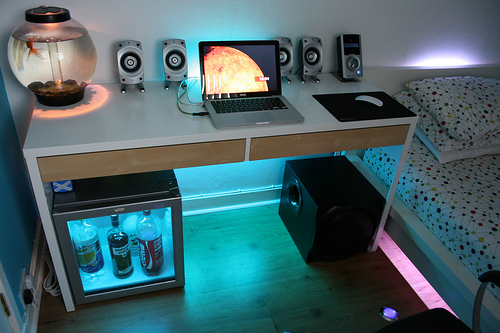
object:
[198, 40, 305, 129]
computer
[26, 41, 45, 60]
goldfish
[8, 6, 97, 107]
aquarium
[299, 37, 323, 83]
speaker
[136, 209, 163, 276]
bottle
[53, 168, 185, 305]
fridge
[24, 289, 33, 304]
outlet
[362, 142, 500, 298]
sheet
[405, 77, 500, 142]
pillow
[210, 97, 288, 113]
keyboard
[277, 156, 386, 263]
sub woofer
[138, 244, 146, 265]
cola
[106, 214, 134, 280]
bottle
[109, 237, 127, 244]
drink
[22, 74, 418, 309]
desk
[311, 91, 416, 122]
mousepad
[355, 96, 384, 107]
mouse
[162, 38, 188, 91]
speaker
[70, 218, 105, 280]
beverages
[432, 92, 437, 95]
color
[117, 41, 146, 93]
speaker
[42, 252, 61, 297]
cord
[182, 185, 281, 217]
baseboard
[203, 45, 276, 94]
screen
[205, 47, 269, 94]
sun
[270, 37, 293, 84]
speaker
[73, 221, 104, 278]
bottle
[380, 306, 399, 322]
cell phone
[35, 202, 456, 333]
floor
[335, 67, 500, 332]
bed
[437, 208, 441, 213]
dot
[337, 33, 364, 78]
clock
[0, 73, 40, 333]
wall